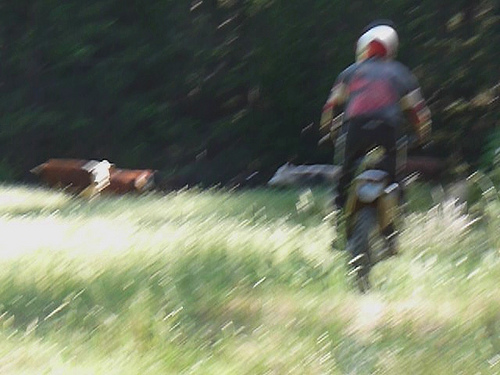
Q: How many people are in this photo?
A: One.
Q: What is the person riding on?
A: Motorbike.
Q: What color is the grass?
A: Green.